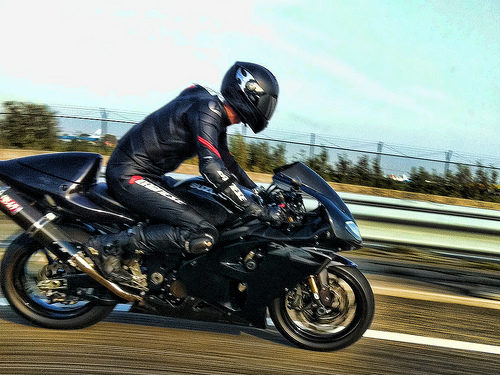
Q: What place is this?
A: It is a road.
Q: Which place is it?
A: It is a road.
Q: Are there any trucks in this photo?
A: No, there are no trucks.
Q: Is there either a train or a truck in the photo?
A: No, there are no trucks or trains.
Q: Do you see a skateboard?
A: No, there are no skateboards.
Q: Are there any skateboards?
A: No, there are no skateboards.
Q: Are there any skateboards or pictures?
A: No, there are no skateboards or pictures.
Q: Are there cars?
A: No, there are no cars.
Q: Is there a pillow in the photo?
A: No, there are no pillows.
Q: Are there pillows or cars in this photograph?
A: No, there are no pillows or cars.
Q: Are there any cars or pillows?
A: No, there are no pillows or cars.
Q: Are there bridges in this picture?
A: Yes, there is a bridge.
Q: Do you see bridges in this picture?
A: Yes, there is a bridge.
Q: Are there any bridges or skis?
A: Yes, there is a bridge.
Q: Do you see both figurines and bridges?
A: No, there is a bridge but no figurines.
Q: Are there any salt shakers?
A: No, there are no salt shakers.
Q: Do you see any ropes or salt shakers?
A: No, there are no salt shakers or ropes.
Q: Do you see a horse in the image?
A: No, there are no horses.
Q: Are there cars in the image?
A: No, there are no cars.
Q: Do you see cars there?
A: No, there are no cars.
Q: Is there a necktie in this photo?
A: No, there are no ties.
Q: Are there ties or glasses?
A: No, there are no ties or glasses.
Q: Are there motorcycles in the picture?
A: Yes, there is a motorcycle.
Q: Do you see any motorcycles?
A: Yes, there is a motorcycle.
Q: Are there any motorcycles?
A: Yes, there is a motorcycle.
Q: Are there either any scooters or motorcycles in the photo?
A: Yes, there is a motorcycle.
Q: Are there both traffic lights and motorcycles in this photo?
A: No, there is a motorcycle but no traffic lights.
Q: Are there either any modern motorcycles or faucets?
A: Yes, there is a modern motorcycle.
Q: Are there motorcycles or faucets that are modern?
A: Yes, the motorcycle is modern.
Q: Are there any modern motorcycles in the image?
A: Yes, there is a modern motorcycle.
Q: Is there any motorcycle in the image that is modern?
A: Yes, there is a motorcycle that is modern.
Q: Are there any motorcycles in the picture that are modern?
A: Yes, there is a motorcycle that is modern.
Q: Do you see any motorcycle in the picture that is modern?
A: Yes, there is a motorcycle that is modern.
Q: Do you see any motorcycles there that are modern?
A: Yes, there is a motorcycle that is modern.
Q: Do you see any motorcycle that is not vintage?
A: Yes, there is a modern motorcycle.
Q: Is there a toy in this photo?
A: No, there are no toys.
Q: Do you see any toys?
A: No, there are no toys.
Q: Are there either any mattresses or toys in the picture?
A: No, there are no toys or mattresses.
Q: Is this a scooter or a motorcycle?
A: This is a motorcycle.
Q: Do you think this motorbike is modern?
A: Yes, the motorbike is modern.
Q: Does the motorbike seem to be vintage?
A: No, the motorbike is modern.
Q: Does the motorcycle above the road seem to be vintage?
A: No, the motorbike is modern.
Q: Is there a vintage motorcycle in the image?
A: No, there is a motorcycle but it is modern.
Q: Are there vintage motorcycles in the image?
A: No, there is a motorcycle but it is modern.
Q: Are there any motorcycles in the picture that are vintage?
A: No, there is a motorcycle but it is modern.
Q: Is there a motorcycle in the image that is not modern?
A: No, there is a motorcycle but it is modern.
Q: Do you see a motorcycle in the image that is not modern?
A: No, there is a motorcycle but it is modern.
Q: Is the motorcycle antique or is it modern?
A: The motorcycle is modern.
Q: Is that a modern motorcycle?
A: Yes, that is a modern motorcycle.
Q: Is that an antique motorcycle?
A: No, that is a modern motorcycle.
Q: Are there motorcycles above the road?
A: Yes, there is a motorcycle above the road.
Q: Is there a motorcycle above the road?
A: Yes, there is a motorcycle above the road.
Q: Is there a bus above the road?
A: No, there is a motorcycle above the road.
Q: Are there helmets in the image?
A: Yes, there is a helmet.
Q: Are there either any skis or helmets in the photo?
A: Yes, there is a helmet.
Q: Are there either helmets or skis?
A: Yes, there is a helmet.